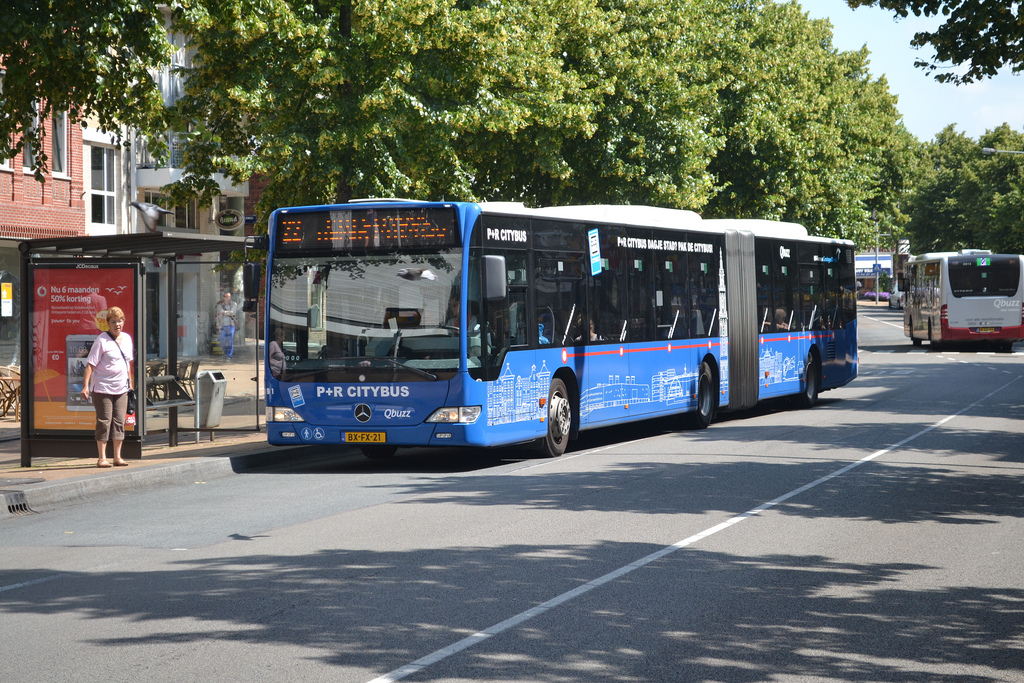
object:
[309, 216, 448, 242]
lcd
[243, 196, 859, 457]
bus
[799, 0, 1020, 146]
sky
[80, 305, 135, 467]
woman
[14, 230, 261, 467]
bus stop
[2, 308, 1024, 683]
road